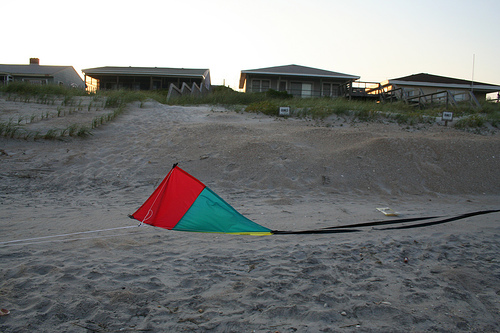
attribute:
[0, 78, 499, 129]
grass — green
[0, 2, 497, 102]
sky — white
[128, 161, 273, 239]
kite — colorful